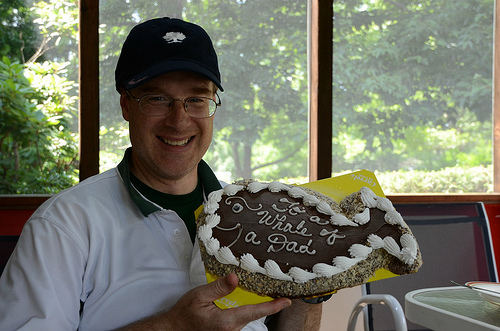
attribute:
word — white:
[271, 195, 306, 215]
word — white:
[303, 209, 329, 224]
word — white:
[315, 224, 345, 246]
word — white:
[256, 209, 311, 239]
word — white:
[263, 231, 315, 256]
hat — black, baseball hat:
[93, 9, 240, 104]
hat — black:
[108, 11, 230, 98]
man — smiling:
[45, 0, 359, 304]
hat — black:
[127, 27, 223, 88]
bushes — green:
[2, 6, 74, 177]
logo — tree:
[152, 22, 187, 52]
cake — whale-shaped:
[190, 172, 425, 303]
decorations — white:
[220, 191, 344, 261]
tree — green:
[36, 1, 396, 183]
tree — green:
[354, 6, 489, 165]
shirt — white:
[3, 143, 273, 329]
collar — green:
[115, 142, 226, 219]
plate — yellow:
[192, 170, 414, 310]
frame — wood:
[314, 0, 335, 178]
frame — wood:
[81, 0, 102, 178]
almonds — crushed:
[197, 251, 424, 295]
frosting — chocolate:
[215, 189, 406, 272]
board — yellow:
[324, 177, 372, 189]